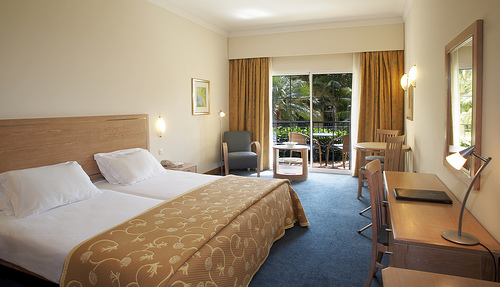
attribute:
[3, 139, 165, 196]
pillows — white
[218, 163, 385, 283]
carpet — blue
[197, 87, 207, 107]
picture — framed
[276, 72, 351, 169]
glass door — sliding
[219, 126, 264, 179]
chair — gray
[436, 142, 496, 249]
lamp — small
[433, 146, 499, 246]
lamp — silver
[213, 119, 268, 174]
chair — grey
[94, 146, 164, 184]
pillow — fluffy, white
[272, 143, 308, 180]
table — small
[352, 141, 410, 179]
table — small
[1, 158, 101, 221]
pillow — fluffy, white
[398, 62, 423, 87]
fixture — light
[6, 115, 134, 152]
headboard — wood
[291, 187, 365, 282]
carpet — blue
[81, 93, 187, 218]
pillow — white, fluffy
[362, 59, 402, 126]
gold drapes — motel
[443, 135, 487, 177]
lamp — on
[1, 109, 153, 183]
head board — light colored, wooden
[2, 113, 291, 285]
bed — king-size, king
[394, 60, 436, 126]
fixture — light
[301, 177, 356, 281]
carpeting — blue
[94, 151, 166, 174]
pillow — white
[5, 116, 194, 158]
headboard — brown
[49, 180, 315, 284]
comforter — brown